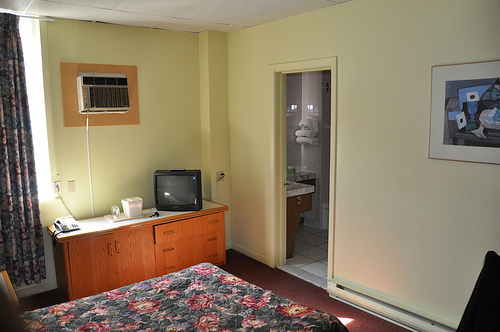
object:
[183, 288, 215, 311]
flower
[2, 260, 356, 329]
bed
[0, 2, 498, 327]
hotel room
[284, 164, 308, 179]
sink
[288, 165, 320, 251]
counter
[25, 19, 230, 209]
wall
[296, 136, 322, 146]
towels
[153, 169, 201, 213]
tv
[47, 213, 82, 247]
telephone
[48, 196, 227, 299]
dresser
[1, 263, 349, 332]
design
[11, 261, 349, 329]
bed spread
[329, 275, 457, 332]
heater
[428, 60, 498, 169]
artwork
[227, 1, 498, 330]
wall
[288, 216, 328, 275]
floor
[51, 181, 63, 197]
outlet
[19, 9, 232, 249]
wall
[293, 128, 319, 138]
towel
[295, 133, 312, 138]
shelf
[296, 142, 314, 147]
shelf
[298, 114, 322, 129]
towel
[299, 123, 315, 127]
shelf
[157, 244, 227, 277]
drawer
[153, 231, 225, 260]
drawer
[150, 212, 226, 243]
drawer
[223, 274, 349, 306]
ground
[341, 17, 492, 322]
wall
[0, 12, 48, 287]
curtain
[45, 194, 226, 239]
top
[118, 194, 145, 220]
container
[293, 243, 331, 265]
tile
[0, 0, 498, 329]
bedroom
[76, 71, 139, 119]
air conditioner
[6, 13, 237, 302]
wall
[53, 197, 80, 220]
cord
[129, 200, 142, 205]
ice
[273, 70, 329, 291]
bathroom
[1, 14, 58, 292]
window